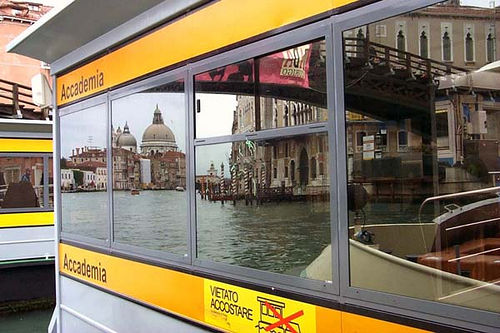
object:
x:
[264, 299, 307, 333]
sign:
[203, 278, 317, 332]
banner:
[178, 41, 310, 87]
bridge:
[310, 37, 499, 137]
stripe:
[45, 0, 213, 83]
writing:
[59, 69, 107, 102]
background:
[0, 0, 499, 333]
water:
[62, 192, 499, 279]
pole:
[220, 163, 228, 208]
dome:
[141, 103, 178, 145]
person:
[35, 59, 57, 122]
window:
[336, 0, 499, 316]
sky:
[62, 92, 237, 178]